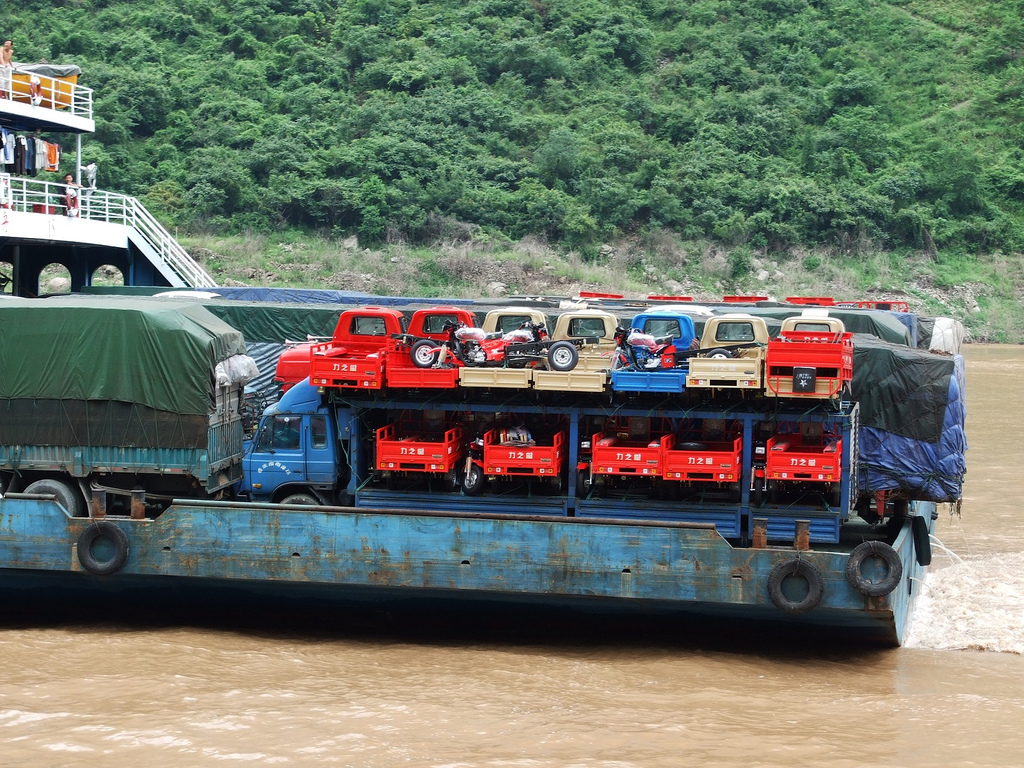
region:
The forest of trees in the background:
[14, 13, 1021, 333]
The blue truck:
[249, 379, 863, 519]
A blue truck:
[251, 374, 877, 534]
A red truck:
[268, 305, 398, 382]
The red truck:
[274, 294, 401, 367]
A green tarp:
[2, 286, 259, 426]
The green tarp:
[4, 291, 246, 421]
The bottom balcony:
[4, 165, 216, 284]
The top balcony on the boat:
[2, 63, 104, 130]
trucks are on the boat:
[190, 225, 963, 696]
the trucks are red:
[327, 403, 849, 511]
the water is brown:
[358, 636, 867, 764]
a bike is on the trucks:
[368, 310, 587, 383]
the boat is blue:
[1, 484, 915, 687]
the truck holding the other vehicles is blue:
[229, 367, 365, 501]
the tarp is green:
[1, 256, 220, 433]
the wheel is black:
[833, 525, 928, 623]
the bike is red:
[399, 317, 552, 379]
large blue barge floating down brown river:
[2, 35, 973, 652]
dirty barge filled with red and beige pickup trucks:
[1, 35, 969, 655]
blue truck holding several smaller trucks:
[236, 300, 857, 545]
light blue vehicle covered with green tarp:
[2, 292, 262, 514]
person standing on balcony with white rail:
[2, 35, 97, 134]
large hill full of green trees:
[2, 0, 1023, 346]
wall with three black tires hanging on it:
[1, 488, 907, 657]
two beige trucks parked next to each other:
[457, 306, 620, 398]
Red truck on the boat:
[280, 291, 401, 397]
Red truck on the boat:
[664, 429, 735, 483]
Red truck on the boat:
[587, 413, 667, 483]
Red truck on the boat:
[471, 423, 576, 491]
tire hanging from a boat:
[840, 541, 908, 605]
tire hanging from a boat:
[62, 518, 143, 588]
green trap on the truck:
[6, 278, 235, 471]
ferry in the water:
[12, 37, 984, 673]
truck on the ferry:
[252, 271, 930, 548]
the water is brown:
[10, 591, 916, 762]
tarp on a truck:
[4, 269, 246, 467]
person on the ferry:
[53, 168, 89, 214]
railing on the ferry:
[6, 176, 128, 234]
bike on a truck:
[429, 316, 591, 370]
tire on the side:
[756, 549, 830, 622]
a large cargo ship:
[19, 64, 971, 674]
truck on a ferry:
[224, 300, 872, 551]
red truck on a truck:
[281, 282, 411, 413]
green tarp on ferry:
[23, 263, 238, 442]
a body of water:
[45, 584, 1017, 765]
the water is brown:
[25, 585, 983, 766]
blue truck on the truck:
[619, 304, 692, 391]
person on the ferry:
[59, 171, 89, 220]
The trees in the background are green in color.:
[2, 0, 1021, 237]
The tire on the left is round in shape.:
[71, 519, 126, 573]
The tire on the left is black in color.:
[73, 517, 125, 569]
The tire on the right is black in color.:
[848, 542, 905, 600]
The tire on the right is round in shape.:
[849, 539, 904, 598]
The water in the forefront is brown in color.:
[2, 617, 1020, 767]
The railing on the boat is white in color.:
[122, 189, 222, 297]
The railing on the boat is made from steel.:
[128, 195, 218, 304]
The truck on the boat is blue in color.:
[244, 306, 865, 528]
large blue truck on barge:
[237, 366, 863, 548]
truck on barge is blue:
[231, 356, 862, 556]